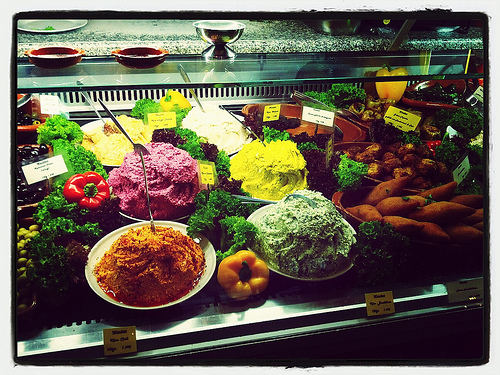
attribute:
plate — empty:
[16, 17, 91, 34]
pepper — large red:
[61, 172, 110, 214]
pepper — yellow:
[215, 244, 269, 299]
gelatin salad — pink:
[101, 142, 202, 219]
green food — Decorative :
[23, 191, 105, 297]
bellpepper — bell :
[66, 171, 111, 210]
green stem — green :
[236, 260, 250, 280]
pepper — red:
[72, 163, 123, 225]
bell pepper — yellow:
[217, 247, 272, 302]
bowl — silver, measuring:
[193, 18, 241, 59]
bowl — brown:
[112, 45, 170, 70]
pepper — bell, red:
[62, 169, 110, 218]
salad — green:
[247, 189, 359, 281]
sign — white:
[17, 151, 69, 183]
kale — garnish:
[185, 188, 257, 260]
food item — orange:
[91, 222, 206, 306]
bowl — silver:
[193, 20, 245, 59]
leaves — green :
[58, 209, 72, 226]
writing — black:
[248, 98, 298, 137]